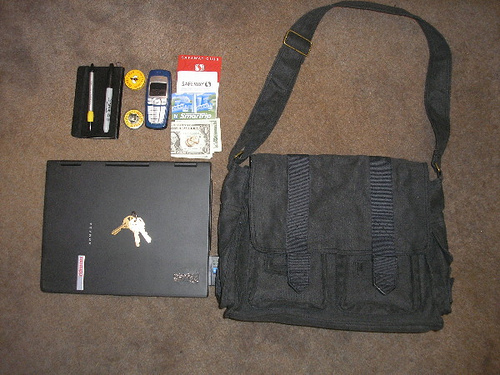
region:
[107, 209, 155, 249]
Keys on the laptop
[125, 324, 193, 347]
Part of the floor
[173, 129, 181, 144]
Part of the money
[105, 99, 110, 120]
Part of the marker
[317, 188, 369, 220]
Part of the bag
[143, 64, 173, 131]
A cellphone on the floor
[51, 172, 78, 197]
Part of the laptop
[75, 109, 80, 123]
Part of the notebook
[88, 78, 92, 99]
Part of the pen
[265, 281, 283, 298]
Part of the pocket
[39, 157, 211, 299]
Closed black laptop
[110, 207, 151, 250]
Shiny metal keys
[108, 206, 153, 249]
Three keys on a keyring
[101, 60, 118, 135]
Black Sharpie marker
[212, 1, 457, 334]
Black laptop satchel with pockets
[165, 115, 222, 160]
Folded one dollar bills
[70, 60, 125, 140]
Pen and marker on a checkbook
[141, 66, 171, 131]
Blue and silver cellphone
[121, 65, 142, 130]
Two metal yellow circles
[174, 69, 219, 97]
White shopping receipt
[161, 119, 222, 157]
money laying on a carpet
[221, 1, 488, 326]
a black computer bag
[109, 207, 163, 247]
a set of keys on a computer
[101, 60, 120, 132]
a shapie maker on a box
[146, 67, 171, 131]
a ceil phone on the carpet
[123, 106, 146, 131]
round yellow stickers on a carpet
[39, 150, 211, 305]
a lap top on a carpet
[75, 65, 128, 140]
a black note book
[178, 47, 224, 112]
a plane ticket on a carpet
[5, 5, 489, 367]
person items on a carpet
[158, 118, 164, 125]
white button on cell phone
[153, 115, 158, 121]
white button on cell phone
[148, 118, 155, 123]
white button on cell phone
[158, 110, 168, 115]
white button on cell phone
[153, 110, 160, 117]
white button on cell phone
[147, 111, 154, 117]
white button on cell phone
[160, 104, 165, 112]
white button on cell phone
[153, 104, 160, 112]
white button on cell phone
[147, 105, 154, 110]
white button on cell phone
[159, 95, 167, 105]
white button on cell phone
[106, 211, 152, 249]
three keys on a key ring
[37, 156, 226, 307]
a black laptop computer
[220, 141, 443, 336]
a black laptop bag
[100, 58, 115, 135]
a black sharpie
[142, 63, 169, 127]
a blue cell phone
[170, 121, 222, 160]
a dollar bill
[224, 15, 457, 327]
a black computer bag with a strap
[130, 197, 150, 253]
two silver keys on a key ring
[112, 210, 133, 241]
a gold key on a key ring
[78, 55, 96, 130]
a ink pen